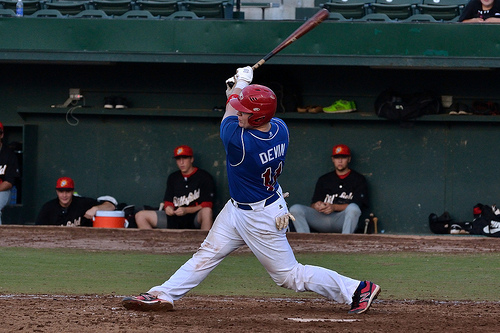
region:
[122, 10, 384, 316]
baseball player swinging his bat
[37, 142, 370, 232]
baseball players sitting in the dugout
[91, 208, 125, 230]
an orange cooler with a white lid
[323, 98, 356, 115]
lime green sneakers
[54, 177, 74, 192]
man wearing a red cap with a white logo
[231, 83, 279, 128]
man wearing a red hard hat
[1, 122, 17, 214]
a man sitting on a bench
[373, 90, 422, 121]
a black back on a shelf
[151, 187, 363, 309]
man wearing white pants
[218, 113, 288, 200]
man wearing a blue uniform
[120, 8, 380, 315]
Baseball player swinging a bat.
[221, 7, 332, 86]
Baseball bat being swung by player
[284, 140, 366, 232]
Baseball player sitting in dugout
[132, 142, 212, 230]
Baseball player sitting in dugout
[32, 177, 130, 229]
Baseball player leaning on orange cooler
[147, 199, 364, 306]
Baseball player wearing white pants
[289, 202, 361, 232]
Baseball player wearing grey pants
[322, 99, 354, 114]
Neon green shoes on shelf in dugout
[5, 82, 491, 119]
Shelf in dugout holding shoes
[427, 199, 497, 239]
Pile of black, red, and white baseball clothes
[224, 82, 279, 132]
Red batting helmet on baseball player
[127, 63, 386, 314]
Batter wearing red helmet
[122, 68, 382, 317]
Batter wearing red shoes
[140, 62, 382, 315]
Batter wearing gray pants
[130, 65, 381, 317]
Batter wearing blue shirt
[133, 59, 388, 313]
Batter wearing white gloves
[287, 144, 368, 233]
player wearing gray pants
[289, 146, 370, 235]
player wearing black shirt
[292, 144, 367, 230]
player wearing red hat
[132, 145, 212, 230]
guy wearing black shirt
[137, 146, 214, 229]
guy wearing black shorts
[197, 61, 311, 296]
baseball player is swinging a bat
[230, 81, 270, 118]
player is wearing a red helmet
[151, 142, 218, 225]
player is sitting in a dugout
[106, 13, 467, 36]
stadium steats over the player dug out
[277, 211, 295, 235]
gloves are in the players back pocket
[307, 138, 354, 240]
player is sitting on a bench in the dug out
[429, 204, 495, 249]
equipment is set in the dug out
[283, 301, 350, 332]
catchers mound surround by clay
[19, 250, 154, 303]
manicured green grass of the baseball field.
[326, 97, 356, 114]
bright neon yellow cleats on a shelf